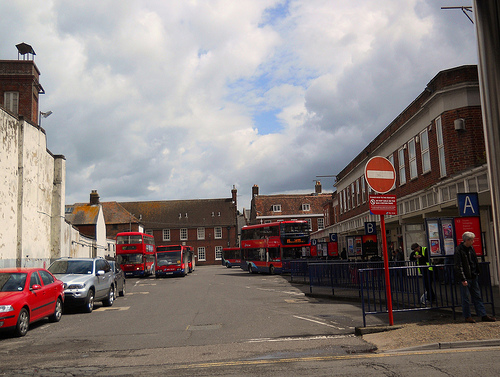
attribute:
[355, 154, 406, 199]
metal sign — red, white, no entry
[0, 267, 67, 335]
car — red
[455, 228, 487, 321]
man — grey haired, short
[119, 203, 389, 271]
buses — red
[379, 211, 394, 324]
post — red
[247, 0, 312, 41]
cloud patch — small, blue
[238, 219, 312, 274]
bus — red, double storied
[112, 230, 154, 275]
bus — double storied, red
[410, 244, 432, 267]
vest — green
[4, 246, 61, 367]
car — red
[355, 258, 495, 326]
railing — black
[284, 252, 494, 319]
fence — short, metal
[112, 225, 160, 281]
bus — large, red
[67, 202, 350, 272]
wall — white, bare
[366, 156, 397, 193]
sign — red, white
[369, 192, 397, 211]
sign — white, red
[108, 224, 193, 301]
vehicle — parked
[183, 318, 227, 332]
pothole — small, repaired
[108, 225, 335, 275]
busses — parked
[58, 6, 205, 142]
clouds — large, white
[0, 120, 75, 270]
building — old, white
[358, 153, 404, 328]
sign pole — red, metal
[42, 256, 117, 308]
car — white, saloon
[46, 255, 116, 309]
vehicle — parked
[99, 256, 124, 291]
vehicle — parked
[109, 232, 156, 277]
vehicle — parked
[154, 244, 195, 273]
vehicle — parked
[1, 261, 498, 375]
pavement — grey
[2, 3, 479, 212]
sky — blue , cloudy